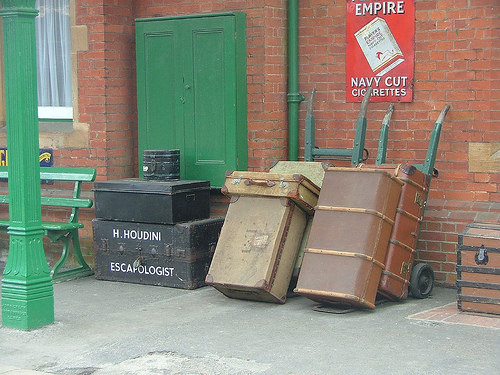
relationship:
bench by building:
[40, 169, 101, 261] [87, 1, 499, 183]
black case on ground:
[87, 218, 223, 290] [14, 225, 427, 373]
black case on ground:
[89, 176, 213, 221] [14, 225, 427, 373]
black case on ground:
[133, 145, 182, 182] [14, 225, 427, 373]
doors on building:
[131, 19, 242, 180] [39, 5, 498, 294]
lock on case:
[472, 239, 487, 270] [455, 220, 500, 315]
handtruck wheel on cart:
[410, 261, 434, 298] [292, 103, 451, 311]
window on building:
[29, 0, 79, 121] [0, 0, 495, 287]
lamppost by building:
[0, 0, 53, 331] [8, 6, 483, 344]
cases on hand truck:
[292, 162, 422, 310] [363, 133, 451, 306]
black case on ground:
[87, 218, 223, 290] [25, 217, 446, 363]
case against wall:
[85, 171, 210, 227] [1, 1, 497, 286]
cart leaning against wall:
[292, 103, 451, 311] [246, 5, 494, 289]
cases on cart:
[292, 162, 422, 310] [292, 103, 451, 311]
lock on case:
[476, 243, 488, 265] [455, 220, 498, 315]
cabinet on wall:
[129, 9, 245, 190] [134, 1, 496, 288]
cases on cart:
[292, 162, 422, 310] [376, 97, 451, 297]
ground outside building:
[0, 280, 499, 371] [0, 0, 495, 287]